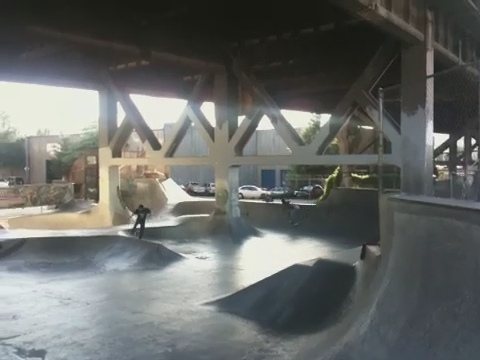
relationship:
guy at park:
[128, 204, 152, 240] [1, 191, 478, 356]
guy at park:
[128, 204, 152, 240] [32, 111, 339, 250]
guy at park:
[128, 204, 152, 240] [9, 10, 473, 357]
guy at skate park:
[126, 200, 156, 239] [0, 185, 477, 357]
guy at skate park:
[128, 204, 152, 240] [3, 3, 478, 358]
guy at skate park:
[128, 204, 152, 240] [79, 244, 357, 332]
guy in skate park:
[128, 204, 152, 240] [0, 185, 477, 357]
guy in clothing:
[128, 204, 152, 240] [130, 206, 149, 237]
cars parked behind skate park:
[176, 180, 319, 199] [0, 185, 477, 357]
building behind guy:
[20, 133, 70, 182] [128, 204, 152, 240]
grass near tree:
[58, 193, 110, 213] [58, 124, 133, 191]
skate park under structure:
[0, 185, 477, 357] [0, 0, 478, 226]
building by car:
[142, 103, 362, 195] [230, 172, 279, 207]